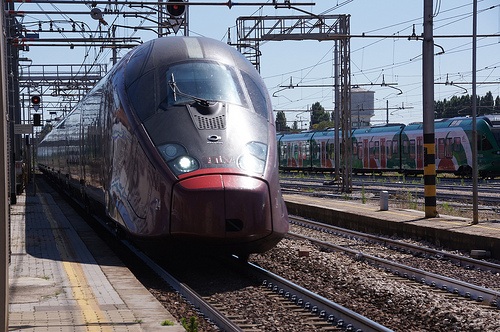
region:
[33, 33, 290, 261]
gray train next to the platform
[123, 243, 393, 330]
metal track in front of the train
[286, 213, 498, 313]
track to the right of track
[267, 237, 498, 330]
gravel next to track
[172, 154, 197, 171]
headlight on the train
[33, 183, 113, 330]
yellow line painted on the platform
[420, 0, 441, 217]
metal pole to the right of train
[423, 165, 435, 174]
yellow stripe painted on pole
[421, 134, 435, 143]
black stripe painted on pole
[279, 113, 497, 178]
green train behind pole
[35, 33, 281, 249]
a red train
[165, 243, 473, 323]
the train tracks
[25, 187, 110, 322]
a yellow stripe on the platform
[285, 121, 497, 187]
a green and red train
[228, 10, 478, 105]
wires above the train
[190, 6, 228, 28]
the sky in the background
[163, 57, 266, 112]
the windshield of the train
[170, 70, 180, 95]
the windshield wiper of the train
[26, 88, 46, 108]
a street light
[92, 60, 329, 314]
th train is black and red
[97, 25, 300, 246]
the train is made of metal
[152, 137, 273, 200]
these are head lights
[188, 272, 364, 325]
these are train tracks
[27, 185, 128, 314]
this is a trian platform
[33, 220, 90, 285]
the platform is made of concrete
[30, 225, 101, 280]
this line is yellow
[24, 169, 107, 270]
this is the train's shadow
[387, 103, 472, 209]
the pole is striped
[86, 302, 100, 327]
yellow paint on platform.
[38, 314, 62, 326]
bricks on the platform.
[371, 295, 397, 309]
pebbles between the tracks.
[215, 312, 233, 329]
track made of steel.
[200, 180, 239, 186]
red paint on the train.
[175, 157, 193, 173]
headlight on the train.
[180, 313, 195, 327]
weeds near the tracks.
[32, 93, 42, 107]
traffic light above platform.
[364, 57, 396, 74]
wires above the tracks.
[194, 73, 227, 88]
windshield on the train.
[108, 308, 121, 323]
brick on side walk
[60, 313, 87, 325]
brick on side walk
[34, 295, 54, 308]
brick on side walk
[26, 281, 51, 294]
brick on side walk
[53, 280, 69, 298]
brick on side walk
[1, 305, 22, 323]
brick on side walk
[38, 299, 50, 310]
brick on side walk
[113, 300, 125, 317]
brick on side walk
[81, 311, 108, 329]
brick on side walk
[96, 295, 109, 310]
brick on side walk